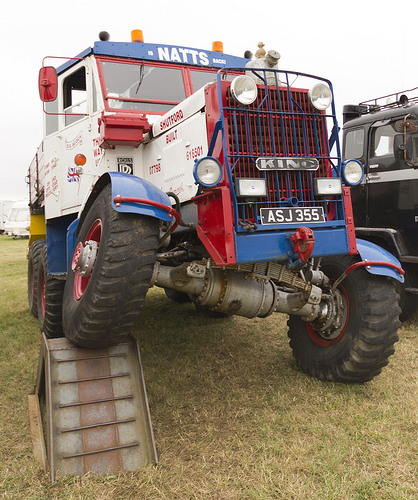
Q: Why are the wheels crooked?
A: One is elevated.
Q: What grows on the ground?
A: Grass.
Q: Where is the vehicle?
A: On the grass.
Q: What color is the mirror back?
A: Red.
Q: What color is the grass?
A: Green.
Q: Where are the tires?
A: On the wheels.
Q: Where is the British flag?
A: On the side of the vehicle.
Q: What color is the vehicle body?
A: Red, white, and blue.